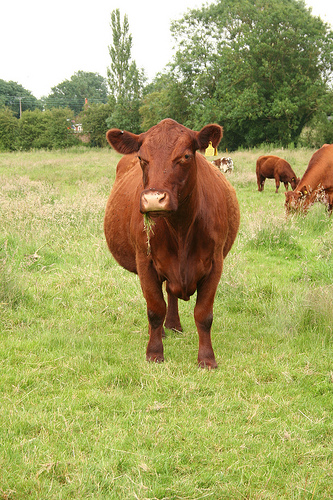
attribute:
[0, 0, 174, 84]
sky — blue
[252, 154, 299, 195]
cow — brown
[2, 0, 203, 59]
clouds — white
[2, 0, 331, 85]
sky — blue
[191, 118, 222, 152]
ear — cow's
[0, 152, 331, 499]
green grass — short, yellow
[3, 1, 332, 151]
trees — green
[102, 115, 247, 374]
cow — brown, dark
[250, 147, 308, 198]
cow — brown, dark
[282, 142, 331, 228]
cow — brown, dark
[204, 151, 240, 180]
cow — brown, dark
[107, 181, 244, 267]
belly — bulky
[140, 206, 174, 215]
mouth — cow's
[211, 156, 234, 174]
cow — brown, white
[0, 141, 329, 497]
grass — green, short, yellow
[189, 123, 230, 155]
ear — cow's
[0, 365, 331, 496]
grass — short, green, yellow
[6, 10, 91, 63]
clouds — white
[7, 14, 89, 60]
clouds — white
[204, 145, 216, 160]
tag — yellow, identification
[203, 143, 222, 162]
tag — yellow